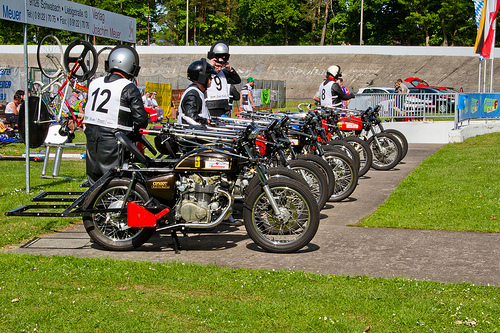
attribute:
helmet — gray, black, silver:
[106, 45, 140, 74]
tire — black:
[242, 173, 319, 252]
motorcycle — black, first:
[84, 129, 321, 254]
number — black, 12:
[88, 87, 111, 114]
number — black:
[212, 73, 222, 90]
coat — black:
[79, 74, 149, 157]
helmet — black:
[188, 58, 218, 89]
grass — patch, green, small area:
[361, 135, 500, 229]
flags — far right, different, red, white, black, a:
[463, 2, 498, 89]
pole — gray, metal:
[18, 24, 36, 197]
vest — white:
[84, 74, 138, 132]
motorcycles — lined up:
[88, 101, 408, 252]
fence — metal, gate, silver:
[343, 89, 469, 128]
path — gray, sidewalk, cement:
[7, 142, 500, 286]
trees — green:
[3, 1, 500, 51]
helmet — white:
[324, 65, 345, 78]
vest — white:
[206, 67, 234, 98]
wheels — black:
[84, 177, 318, 253]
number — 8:
[319, 88, 329, 104]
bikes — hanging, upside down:
[34, 31, 109, 128]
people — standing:
[88, 46, 242, 188]